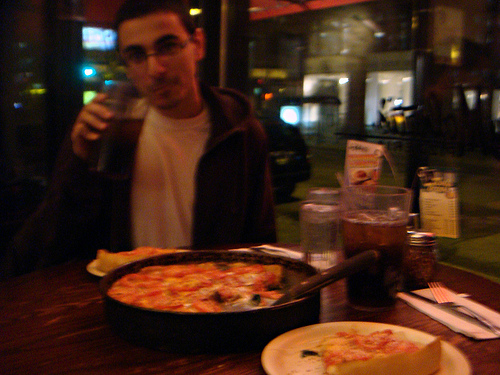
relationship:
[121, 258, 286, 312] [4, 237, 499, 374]
pizza on table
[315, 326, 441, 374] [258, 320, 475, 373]
food on plate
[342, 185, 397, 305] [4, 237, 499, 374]
drink on table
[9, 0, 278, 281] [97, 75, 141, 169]
guy holding drink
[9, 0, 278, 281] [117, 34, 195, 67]
guy wearing eye glass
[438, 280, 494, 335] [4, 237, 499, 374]
fork on table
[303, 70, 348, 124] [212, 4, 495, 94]
window in background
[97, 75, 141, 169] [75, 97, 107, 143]
drink in hand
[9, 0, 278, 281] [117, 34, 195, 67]
guy has eye glass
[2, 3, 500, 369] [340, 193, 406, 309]
picture of pop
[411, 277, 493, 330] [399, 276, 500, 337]
silverwear on napkin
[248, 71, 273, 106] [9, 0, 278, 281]
lights behind guy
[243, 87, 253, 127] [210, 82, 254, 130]
edge of hood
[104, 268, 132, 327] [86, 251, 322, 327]
edge of sufuria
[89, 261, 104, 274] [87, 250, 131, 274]
edge of plate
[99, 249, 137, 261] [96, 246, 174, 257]
edge of food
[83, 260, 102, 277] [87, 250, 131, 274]
part of plate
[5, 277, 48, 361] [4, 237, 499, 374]
part of table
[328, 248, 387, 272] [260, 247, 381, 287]
part of handle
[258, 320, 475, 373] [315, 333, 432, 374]
plate of food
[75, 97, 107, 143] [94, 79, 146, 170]
hand holding glass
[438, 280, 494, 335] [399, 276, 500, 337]
fork on napkin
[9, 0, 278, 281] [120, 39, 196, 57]
guy has eye glass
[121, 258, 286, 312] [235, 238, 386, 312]
pizza with pizza cutter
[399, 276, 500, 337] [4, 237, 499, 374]
napkin on table